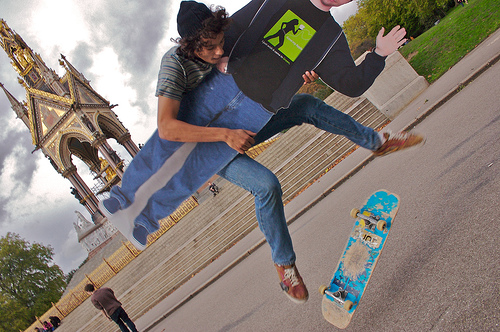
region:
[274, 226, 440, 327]
Blue wooden skareboard in the air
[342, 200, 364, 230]
Small yellow wheel on a skateboard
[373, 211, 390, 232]
Small yellow wheel on a skateboard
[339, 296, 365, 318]
Small yellow wheel on a skateboard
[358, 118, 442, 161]
Red and white shoe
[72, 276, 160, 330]
Man standing on the pavement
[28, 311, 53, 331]
Tall yellow metal fence post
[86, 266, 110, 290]
Tall yellow metal fence post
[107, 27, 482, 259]
the man is holding a sign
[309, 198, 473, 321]
the boy has a skateboard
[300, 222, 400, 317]
the boy has a blue skateboard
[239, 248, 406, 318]
the boy is wearing brown shoes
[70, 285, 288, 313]
the man is wearing a brown shirt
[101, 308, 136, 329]
the man is wearing black pants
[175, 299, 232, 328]
the cement is gray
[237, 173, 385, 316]
the boy is wearing jeans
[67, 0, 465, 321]
man above blue skatboard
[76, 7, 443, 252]
man holding cut out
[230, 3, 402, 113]
cut out has black shirt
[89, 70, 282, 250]
cut out wearing wearing blue jeans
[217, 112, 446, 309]
man wearing brown shoes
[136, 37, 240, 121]
man wearing striped shirt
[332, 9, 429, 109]
cut out has arm up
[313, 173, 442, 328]
grey trim on skateboard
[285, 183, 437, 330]
the skateboard in the air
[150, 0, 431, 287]
the skatboarder doing a trick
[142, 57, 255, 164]
the arm hiolding the cardboard cutout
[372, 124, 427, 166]
the rbown shoe on the foot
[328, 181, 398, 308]
the blue base of the skateboard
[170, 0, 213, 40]
the black cap on the skateboarders head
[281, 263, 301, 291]
the white lace on the shoe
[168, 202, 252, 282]
the steps behind the skateboarder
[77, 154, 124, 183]
the statue in the monument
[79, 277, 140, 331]
the man in the road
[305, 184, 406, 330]
blue colored skateboard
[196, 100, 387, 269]
blue jeans on a skater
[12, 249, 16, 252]
A green leaf on a plant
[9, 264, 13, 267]
A green leaf on a plant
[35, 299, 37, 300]
A green leaf on a plant